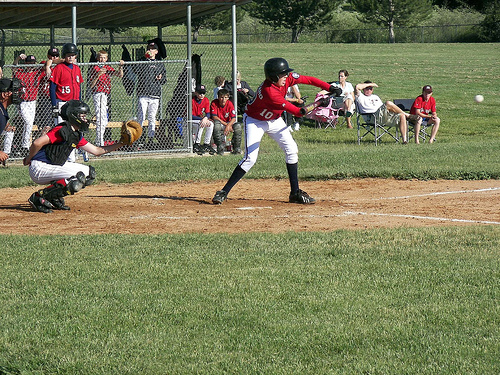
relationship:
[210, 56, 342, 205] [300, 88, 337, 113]
he holding bat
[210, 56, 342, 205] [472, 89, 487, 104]
he preparing to ball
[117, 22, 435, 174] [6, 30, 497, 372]
people watching game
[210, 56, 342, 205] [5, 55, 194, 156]
he standing behind fence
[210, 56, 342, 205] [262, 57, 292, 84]
he wearing a hat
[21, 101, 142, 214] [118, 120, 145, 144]
catcher holding glove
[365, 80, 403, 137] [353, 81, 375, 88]
man is covering face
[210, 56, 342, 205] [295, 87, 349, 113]
he is holding baseball bat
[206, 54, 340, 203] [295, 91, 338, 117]
he is at baseball bat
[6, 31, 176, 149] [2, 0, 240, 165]
players in dugout